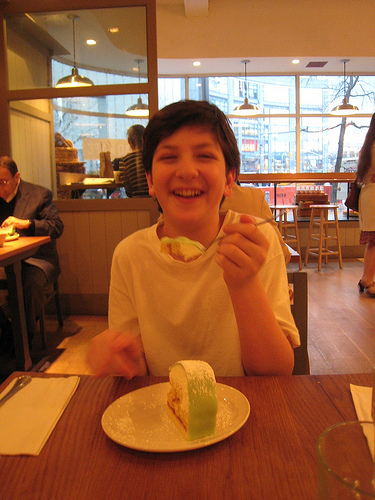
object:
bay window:
[158, 71, 375, 172]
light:
[54, 15, 95, 92]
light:
[85, 38, 96, 47]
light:
[190, 60, 201, 66]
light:
[291, 59, 301, 65]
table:
[0, 370, 375, 500]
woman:
[345, 111, 375, 298]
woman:
[114, 123, 149, 203]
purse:
[342, 181, 362, 212]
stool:
[268, 202, 301, 272]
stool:
[304, 202, 344, 272]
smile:
[162, 172, 210, 209]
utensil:
[1, 373, 32, 407]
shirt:
[101, 212, 302, 380]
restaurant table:
[0, 231, 57, 372]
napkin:
[349, 379, 373, 462]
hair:
[142, 99, 239, 178]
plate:
[98, 380, 250, 453]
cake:
[165, 356, 219, 441]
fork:
[159, 209, 291, 257]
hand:
[213, 214, 269, 282]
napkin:
[0, 373, 85, 459]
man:
[1, 154, 64, 355]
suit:
[1, 179, 64, 341]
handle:
[7, 365, 32, 392]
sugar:
[95, 381, 180, 455]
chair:
[282, 269, 310, 378]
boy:
[91, 99, 299, 379]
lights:
[228, 59, 263, 117]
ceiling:
[29, 1, 374, 77]